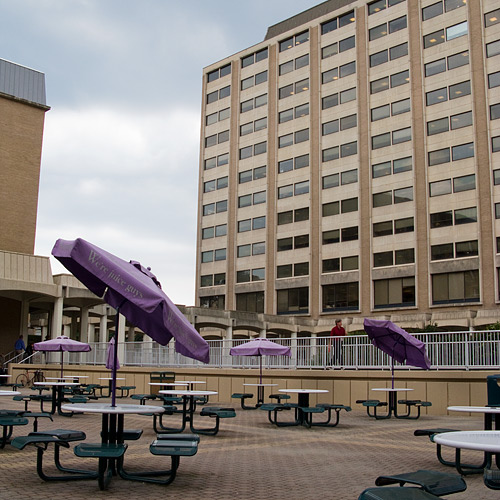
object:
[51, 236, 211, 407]
umbrella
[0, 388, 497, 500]
patio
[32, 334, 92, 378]
umbrellas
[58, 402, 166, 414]
table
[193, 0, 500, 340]
building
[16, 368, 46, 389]
bike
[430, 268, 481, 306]
windows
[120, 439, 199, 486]
seats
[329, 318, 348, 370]
man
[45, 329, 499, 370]
fencing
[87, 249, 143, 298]
writing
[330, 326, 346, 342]
shirt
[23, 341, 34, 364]
person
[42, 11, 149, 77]
cloud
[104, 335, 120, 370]
umbrella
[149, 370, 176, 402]
can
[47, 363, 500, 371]
walkway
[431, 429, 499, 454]
tables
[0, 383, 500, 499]
seating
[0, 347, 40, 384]
stairs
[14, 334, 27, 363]
man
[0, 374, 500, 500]
layout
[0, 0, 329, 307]
sky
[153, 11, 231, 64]
clouds